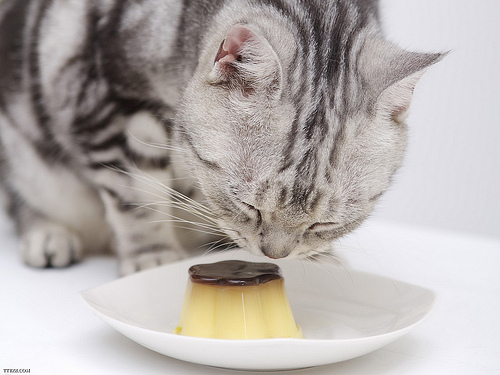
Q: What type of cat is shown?
A: Cat.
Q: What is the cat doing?
A: Eating.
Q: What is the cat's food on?
A: Bowl.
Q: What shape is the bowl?
A: Round.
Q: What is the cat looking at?
A: Food.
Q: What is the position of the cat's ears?
A: Up.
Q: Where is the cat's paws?
A: On the table.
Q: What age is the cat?
A: Kitten.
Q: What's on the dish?
A: Cake.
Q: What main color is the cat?
A: Gray.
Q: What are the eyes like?
A: Closed.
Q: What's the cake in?
A: Bowl.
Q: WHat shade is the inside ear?
A: Pink.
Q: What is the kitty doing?
A: Eating.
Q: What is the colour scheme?
A: White.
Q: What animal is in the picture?
A: A cat.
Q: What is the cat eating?
A: Pudding.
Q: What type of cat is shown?
A: Grey striped tabby.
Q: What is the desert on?
A: A white plate.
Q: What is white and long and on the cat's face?
A: Whiskers.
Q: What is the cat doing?
A: Sniffing.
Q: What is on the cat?
A: Whiskers.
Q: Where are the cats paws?
A: On the floor.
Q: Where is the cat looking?
A: The plate.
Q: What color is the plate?
A: White.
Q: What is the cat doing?
A: Sniffing.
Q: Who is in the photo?
A: Nobody.